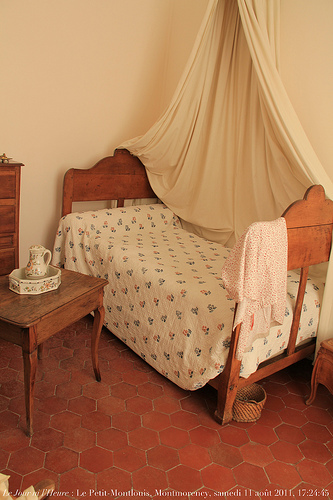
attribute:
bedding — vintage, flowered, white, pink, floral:
[52, 206, 323, 392]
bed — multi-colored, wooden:
[50, 149, 330, 425]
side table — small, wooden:
[303, 337, 332, 404]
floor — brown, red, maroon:
[1, 315, 331, 498]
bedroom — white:
[0, 0, 332, 497]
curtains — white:
[120, 1, 332, 248]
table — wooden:
[0, 270, 111, 436]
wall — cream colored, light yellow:
[0, 1, 330, 274]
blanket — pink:
[222, 220, 289, 359]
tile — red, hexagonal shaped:
[166, 464, 204, 492]